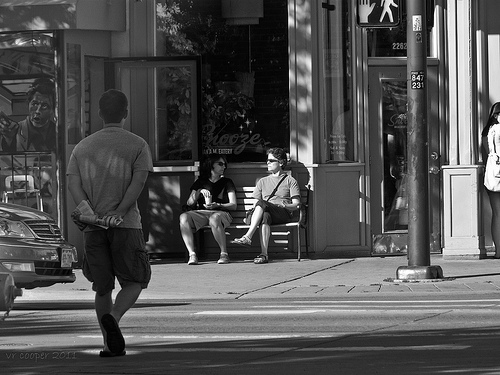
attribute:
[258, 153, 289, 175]
sunglasses — dark, black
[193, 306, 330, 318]
white line — long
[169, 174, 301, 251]
bench — wooden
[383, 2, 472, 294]
lamp — metal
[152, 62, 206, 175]
window — open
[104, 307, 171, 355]
shoe — man's